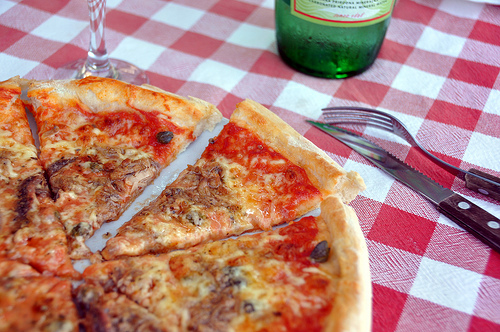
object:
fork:
[321, 104, 499, 197]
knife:
[307, 118, 500, 263]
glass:
[275, 1, 387, 79]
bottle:
[272, 0, 397, 81]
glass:
[50, 0, 150, 86]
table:
[4, 0, 500, 332]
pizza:
[0, 74, 371, 330]